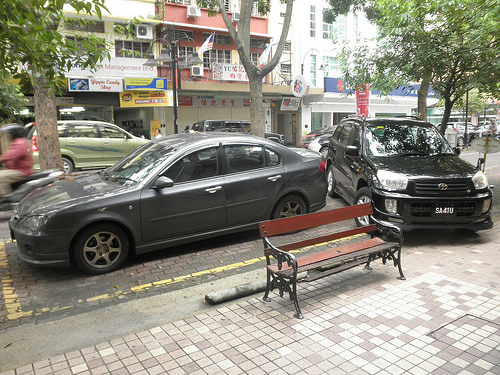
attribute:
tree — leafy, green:
[325, 0, 499, 137]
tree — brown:
[5, 2, 102, 192]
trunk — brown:
[26, 75, 73, 155]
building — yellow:
[19, 1, 154, 136]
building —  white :
[0, 0, 499, 142]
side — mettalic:
[259, 232, 302, 320]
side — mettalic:
[364, 202, 407, 278]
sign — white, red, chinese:
[217, 62, 245, 79]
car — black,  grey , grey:
[8, 132, 335, 280]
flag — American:
[200, 32, 214, 53]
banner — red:
[351, 80, 372, 117]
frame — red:
[156, 7, 265, 56]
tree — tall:
[196, 1, 293, 137]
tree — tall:
[365, 4, 499, 158]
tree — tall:
[0, 1, 98, 168]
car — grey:
[7, 112, 328, 276]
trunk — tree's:
[261, 117, 329, 205]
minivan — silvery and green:
[10, 91, 157, 193]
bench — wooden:
[218, 194, 430, 295]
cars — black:
[10, 117, 493, 276]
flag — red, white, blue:
[199, 34, 214, 54]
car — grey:
[192, 120, 286, 145]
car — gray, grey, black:
[24, 129, 322, 266]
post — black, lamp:
[169, 48, 179, 132]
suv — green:
[110, 103, 128, 168]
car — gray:
[393, 113, 457, 143]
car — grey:
[198, 151, 226, 282]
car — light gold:
[27, 120, 150, 174]